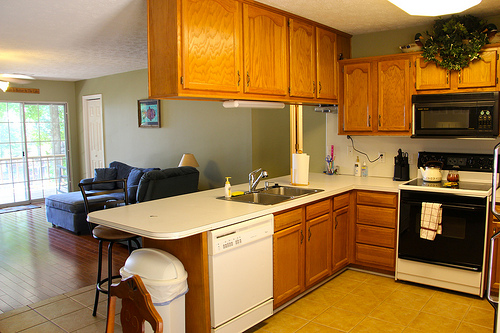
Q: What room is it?
A: It is a kitchen.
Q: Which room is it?
A: It is a kitchen.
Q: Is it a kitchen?
A: Yes, it is a kitchen.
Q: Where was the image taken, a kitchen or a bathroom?
A: It was taken at a kitchen.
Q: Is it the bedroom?
A: No, it is the kitchen.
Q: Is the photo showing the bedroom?
A: No, the picture is showing the kitchen.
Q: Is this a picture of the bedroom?
A: No, the picture is showing the kitchen.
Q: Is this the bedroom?
A: No, it is the kitchen.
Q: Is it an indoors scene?
A: Yes, it is indoors.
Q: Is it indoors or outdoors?
A: It is indoors.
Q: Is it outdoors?
A: No, it is indoors.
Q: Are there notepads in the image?
A: No, there are no notepads.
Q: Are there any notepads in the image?
A: No, there are no notepads.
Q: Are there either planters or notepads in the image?
A: No, there are no notepads or planters.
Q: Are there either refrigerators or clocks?
A: No, there are no clocks or refrigerators.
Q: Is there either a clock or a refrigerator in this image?
A: No, there are no clocks or refrigerators.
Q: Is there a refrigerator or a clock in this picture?
A: No, there are no clocks or refrigerators.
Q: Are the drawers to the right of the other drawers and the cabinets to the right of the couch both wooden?
A: Yes, both the drawers and the cabinets are wooden.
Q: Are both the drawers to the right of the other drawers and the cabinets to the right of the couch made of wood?
A: Yes, both the drawers and the cabinets are made of wood.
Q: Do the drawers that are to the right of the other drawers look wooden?
A: Yes, the drawers are wooden.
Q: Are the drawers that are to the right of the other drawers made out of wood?
A: Yes, the drawers are made of wood.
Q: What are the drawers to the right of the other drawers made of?
A: The drawers are made of wood.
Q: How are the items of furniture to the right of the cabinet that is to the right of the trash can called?
A: The pieces of furniture are drawers.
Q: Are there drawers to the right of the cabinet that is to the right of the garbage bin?
A: Yes, there are drawers to the right of the cabinet.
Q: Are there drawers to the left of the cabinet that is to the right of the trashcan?
A: No, the drawers are to the right of the cabinet.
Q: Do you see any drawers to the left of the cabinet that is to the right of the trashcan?
A: No, the drawers are to the right of the cabinet.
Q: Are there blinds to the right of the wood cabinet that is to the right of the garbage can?
A: No, there are drawers to the right of the cabinet.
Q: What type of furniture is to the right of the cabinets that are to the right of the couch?
A: The pieces of furniture are drawers.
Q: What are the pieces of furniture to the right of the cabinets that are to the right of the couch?
A: The pieces of furniture are drawers.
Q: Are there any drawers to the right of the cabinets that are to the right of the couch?
A: Yes, there are drawers to the right of the cabinets.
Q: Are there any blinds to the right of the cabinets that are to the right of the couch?
A: No, there are drawers to the right of the cabinets.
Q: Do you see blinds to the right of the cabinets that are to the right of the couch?
A: No, there are drawers to the right of the cabinets.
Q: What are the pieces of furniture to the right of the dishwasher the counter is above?
A: The pieces of furniture are drawers.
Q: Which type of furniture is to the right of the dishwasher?
A: The pieces of furniture are drawers.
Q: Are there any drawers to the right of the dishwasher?
A: Yes, there are drawers to the right of the dishwasher.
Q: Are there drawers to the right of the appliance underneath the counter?
A: Yes, there are drawers to the right of the dishwasher.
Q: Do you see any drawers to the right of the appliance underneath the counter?
A: Yes, there are drawers to the right of the dishwasher.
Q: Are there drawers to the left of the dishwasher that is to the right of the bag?
A: No, the drawers are to the right of the dishwasher.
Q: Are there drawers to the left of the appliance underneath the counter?
A: No, the drawers are to the right of the dishwasher.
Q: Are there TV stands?
A: No, there are no TV stands.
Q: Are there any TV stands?
A: No, there are no TV stands.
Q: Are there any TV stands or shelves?
A: No, there are no TV stands or shelves.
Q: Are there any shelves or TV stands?
A: No, there are no TV stands or shelves.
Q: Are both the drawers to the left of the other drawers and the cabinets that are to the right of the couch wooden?
A: Yes, both the drawers and the cabinets are wooden.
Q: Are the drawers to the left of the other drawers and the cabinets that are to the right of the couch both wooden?
A: Yes, both the drawers and the cabinets are wooden.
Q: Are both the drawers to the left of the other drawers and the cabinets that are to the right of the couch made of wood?
A: Yes, both the drawers and the cabinets are made of wood.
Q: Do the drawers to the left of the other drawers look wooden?
A: Yes, the drawers are wooden.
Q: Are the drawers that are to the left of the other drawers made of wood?
A: Yes, the drawers are made of wood.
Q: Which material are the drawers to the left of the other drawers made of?
A: The drawers are made of wood.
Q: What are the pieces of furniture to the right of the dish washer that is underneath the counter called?
A: The pieces of furniture are drawers.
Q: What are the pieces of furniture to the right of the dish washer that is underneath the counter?
A: The pieces of furniture are drawers.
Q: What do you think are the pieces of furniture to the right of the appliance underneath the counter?
A: The pieces of furniture are drawers.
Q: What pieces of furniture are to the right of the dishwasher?
A: The pieces of furniture are drawers.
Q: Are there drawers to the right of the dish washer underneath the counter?
A: Yes, there are drawers to the right of the dishwasher.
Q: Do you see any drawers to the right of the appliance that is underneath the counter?
A: Yes, there are drawers to the right of the dishwasher.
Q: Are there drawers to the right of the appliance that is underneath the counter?
A: Yes, there are drawers to the right of the dishwasher.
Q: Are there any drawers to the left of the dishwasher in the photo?
A: No, the drawers are to the right of the dishwasher.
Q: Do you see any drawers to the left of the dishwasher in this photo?
A: No, the drawers are to the right of the dishwasher.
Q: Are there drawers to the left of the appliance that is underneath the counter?
A: No, the drawers are to the right of the dishwasher.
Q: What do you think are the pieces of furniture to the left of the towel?
A: The pieces of furniture are drawers.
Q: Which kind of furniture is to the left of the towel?
A: The pieces of furniture are drawers.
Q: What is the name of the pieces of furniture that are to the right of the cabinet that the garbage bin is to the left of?
A: The pieces of furniture are drawers.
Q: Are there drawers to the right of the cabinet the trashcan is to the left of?
A: Yes, there are drawers to the right of the cabinet.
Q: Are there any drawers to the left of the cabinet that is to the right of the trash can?
A: No, the drawers are to the right of the cabinet.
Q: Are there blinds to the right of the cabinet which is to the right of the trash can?
A: No, there are drawers to the right of the cabinet.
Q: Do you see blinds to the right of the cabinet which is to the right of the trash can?
A: No, there are drawers to the right of the cabinet.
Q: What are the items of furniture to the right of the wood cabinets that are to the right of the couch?
A: The pieces of furniture are drawers.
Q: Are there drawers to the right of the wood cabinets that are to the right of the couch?
A: Yes, there are drawers to the right of the cabinets.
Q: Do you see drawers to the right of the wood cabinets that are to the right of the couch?
A: Yes, there are drawers to the right of the cabinets.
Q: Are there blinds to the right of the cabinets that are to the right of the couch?
A: No, there are drawers to the right of the cabinets.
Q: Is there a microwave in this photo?
A: Yes, there is a microwave.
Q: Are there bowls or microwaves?
A: Yes, there is a microwave.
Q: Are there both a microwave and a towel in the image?
A: Yes, there are both a microwave and a towel.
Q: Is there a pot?
A: No, there are no pots.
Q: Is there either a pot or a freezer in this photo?
A: No, there are no pots or refrigerators.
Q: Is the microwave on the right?
A: Yes, the microwave is on the right of the image.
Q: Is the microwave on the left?
A: No, the microwave is on the right of the image.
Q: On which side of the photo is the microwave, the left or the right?
A: The microwave is on the right of the image.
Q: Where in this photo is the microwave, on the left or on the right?
A: The microwave is on the right of the image.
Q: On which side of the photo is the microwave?
A: The microwave is on the right of the image.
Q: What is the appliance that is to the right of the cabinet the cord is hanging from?
A: The appliance is a microwave.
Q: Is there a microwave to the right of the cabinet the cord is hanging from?
A: Yes, there is a microwave to the right of the cabinet.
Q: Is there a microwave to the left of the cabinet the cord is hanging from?
A: No, the microwave is to the right of the cabinet.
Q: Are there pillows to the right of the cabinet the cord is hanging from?
A: No, there is a microwave to the right of the cabinet.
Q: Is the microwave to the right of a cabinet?
A: Yes, the microwave is to the right of a cabinet.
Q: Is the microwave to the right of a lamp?
A: No, the microwave is to the right of a cabinet.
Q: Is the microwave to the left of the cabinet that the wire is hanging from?
A: No, the microwave is to the right of the cabinet.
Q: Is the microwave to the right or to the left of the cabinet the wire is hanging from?
A: The microwave is to the right of the cabinet.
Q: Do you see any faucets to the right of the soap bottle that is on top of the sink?
A: Yes, there is a faucet to the right of the soap bottle.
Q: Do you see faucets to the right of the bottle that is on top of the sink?
A: Yes, there is a faucet to the right of the soap bottle.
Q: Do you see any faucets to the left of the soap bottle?
A: No, the faucet is to the right of the soap bottle.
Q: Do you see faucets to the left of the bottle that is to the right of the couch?
A: No, the faucet is to the right of the soap bottle.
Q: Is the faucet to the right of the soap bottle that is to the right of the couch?
A: Yes, the faucet is to the right of the soap bottle.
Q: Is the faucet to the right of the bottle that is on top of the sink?
A: Yes, the faucet is to the right of the soap bottle.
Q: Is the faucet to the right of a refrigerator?
A: No, the faucet is to the right of the soap bottle.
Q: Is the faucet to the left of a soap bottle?
A: No, the faucet is to the right of a soap bottle.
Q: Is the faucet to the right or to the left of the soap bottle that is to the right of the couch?
A: The faucet is to the right of the soap bottle.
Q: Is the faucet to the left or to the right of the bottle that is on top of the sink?
A: The faucet is to the right of the soap bottle.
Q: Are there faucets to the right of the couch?
A: Yes, there is a faucet to the right of the couch.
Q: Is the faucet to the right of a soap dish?
A: No, the faucet is to the right of the couch.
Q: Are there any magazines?
A: No, there are no magazines.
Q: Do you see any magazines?
A: No, there are no magazines.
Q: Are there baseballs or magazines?
A: No, there are no magazines or baseballs.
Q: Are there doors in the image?
A: Yes, there is a door.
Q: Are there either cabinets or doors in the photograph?
A: Yes, there is a door.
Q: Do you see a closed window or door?
A: Yes, there is a closed door.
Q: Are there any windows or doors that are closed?
A: Yes, the door is closed.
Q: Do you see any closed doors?
A: Yes, there is a closed door.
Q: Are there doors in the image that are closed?
A: Yes, there is a door that is closed.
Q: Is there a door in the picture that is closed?
A: Yes, there is a door that is closed.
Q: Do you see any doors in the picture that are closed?
A: Yes, there is a door that is closed.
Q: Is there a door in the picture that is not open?
A: Yes, there is an closed door.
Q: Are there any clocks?
A: No, there are no clocks.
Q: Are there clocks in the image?
A: No, there are no clocks.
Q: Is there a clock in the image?
A: No, there are no clocks.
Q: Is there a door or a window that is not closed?
A: No, there is a door but it is closed.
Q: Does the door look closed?
A: Yes, the door is closed.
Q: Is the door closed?
A: Yes, the door is closed.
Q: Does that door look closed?
A: Yes, the door is closed.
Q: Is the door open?
A: No, the door is closed.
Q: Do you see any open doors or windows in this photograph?
A: No, there is a door but it is closed.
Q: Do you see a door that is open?
A: No, there is a door but it is closed.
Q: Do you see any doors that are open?
A: No, there is a door but it is closed.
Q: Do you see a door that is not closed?
A: No, there is a door but it is closed.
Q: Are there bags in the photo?
A: Yes, there is a bag.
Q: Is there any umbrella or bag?
A: Yes, there is a bag.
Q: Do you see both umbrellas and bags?
A: No, there is a bag but no umbrellas.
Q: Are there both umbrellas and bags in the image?
A: No, there is a bag but no umbrellas.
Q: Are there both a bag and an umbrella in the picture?
A: No, there is a bag but no umbrellas.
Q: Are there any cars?
A: No, there are no cars.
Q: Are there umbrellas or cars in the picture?
A: No, there are no cars or umbrellas.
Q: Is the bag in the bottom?
A: Yes, the bag is in the bottom of the image.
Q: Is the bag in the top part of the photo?
A: No, the bag is in the bottom of the image.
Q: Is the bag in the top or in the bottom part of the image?
A: The bag is in the bottom of the image.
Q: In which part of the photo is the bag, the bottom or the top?
A: The bag is in the bottom of the image.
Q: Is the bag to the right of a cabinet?
A: No, the bag is to the left of a cabinet.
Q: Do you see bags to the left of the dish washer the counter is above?
A: Yes, there is a bag to the left of the dishwasher.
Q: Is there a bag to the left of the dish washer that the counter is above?
A: Yes, there is a bag to the left of the dishwasher.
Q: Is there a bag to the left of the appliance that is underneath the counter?
A: Yes, there is a bag to the left of the dishwasher.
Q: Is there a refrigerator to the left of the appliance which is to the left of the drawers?
A: No, there is a bag to the left of the dishwasher.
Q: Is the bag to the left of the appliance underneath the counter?
A: Yes, the bag is to the left of the dishwasher.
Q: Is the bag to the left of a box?
A: No, the bag is to the left of the dishwasher.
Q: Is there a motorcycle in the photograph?
A: No, there are no motorcycles.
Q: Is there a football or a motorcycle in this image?
A: No, there are no motorcycles or footballs.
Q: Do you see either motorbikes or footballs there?
A: No, there are no motorbikes or footballs.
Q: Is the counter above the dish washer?
A: Yes, the counter is above the dish washer.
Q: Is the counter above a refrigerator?
A: No, the counter is above the dish washer.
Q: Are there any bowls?
A: No, there are no bowls.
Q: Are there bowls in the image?
A: No, there are no bowls.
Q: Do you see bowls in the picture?
A: No, there are no bowls.